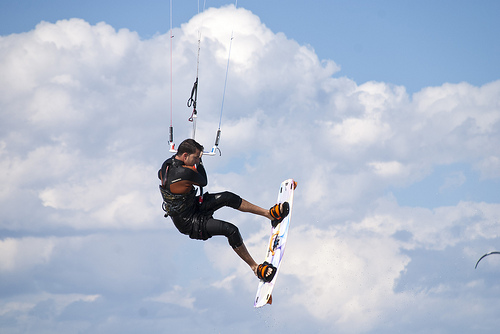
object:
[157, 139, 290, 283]
man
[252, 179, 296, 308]
surfboard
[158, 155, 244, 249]
clothing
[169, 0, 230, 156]
ropes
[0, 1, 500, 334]
sky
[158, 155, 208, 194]
shirt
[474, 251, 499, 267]
parachute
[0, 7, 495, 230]
clouds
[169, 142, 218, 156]
bar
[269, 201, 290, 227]
feet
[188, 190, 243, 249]
pants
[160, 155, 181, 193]
harness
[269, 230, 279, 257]
graffiti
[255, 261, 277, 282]
straps